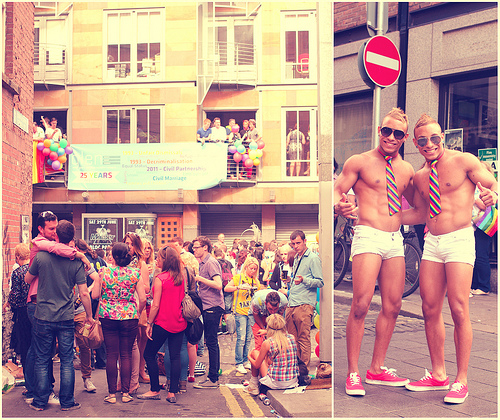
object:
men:
[331, 106, 416, 396]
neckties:
[426, 147, 446, 218]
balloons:
[50, 160, 62, 172]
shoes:
[441, 380, 468, 405]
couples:
[330, 107, 499, 405]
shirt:
[150, 269, 188, 335]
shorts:
[419, 225, 475, 270]